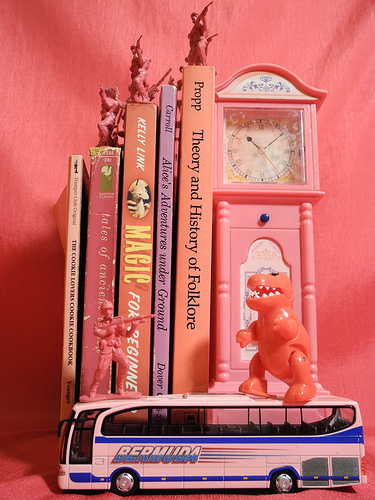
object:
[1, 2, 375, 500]
background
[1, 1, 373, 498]
pink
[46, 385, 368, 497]
tour bus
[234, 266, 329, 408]
tyrannosaurus rex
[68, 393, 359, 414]
roof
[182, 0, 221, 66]
toy soldier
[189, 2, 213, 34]
gun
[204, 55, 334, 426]
grandfather clock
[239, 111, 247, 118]
scratch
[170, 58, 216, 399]
book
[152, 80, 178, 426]
book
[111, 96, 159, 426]
book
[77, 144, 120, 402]
book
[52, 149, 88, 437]
book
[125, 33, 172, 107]
toy soldier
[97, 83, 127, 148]
toy soldier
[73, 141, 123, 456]
cover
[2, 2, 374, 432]
wall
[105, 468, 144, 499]
wheel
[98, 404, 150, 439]
window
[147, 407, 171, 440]
window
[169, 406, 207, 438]
window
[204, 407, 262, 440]
window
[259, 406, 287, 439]
window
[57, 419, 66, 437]
rear view mirror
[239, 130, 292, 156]
hands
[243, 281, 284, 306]
teeth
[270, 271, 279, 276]
eye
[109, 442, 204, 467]
writing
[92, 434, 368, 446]
line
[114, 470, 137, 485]
part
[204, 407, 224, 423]
part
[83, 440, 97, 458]
part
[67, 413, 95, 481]
door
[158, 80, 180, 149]
part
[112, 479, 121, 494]
edge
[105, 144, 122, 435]
side